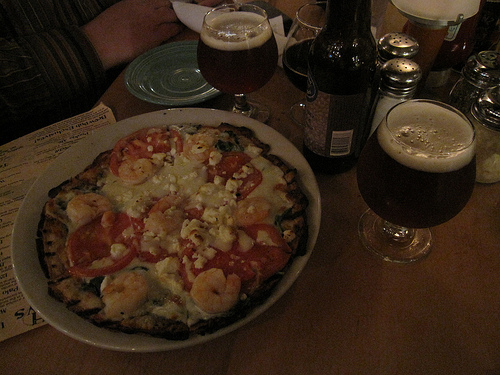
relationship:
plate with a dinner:
[11, 110, 313, 350] [39, 122, 306, 339]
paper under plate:
[2, 113, 34, 345] [11, 110, 313, 350]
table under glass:
[367, 225, 493, 287] [363, 93, 485, 274]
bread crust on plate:
[129, 315, 188, 338] [11, 110, 313, 350]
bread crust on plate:
[227, 290, 274, 315] [11, 110, 313, 350]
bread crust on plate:
[50, 144, 107, 191] [11, 110, 313, 350]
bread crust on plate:
[41, 220, 84, 304] [11, 110, 313, 350]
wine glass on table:
[358, 85, 486, 282] [20, 25, 487, 365]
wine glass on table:
[188, 4, 355, 120] [20, 25, 487, 365]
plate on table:
[11, 110, 313, 350] [20, 25, 487, 365]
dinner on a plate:
[32, 122, 311, 341] [11, 110, 313, 350]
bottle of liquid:
[300, 0, 375, 175] [316, 0, 376, 174]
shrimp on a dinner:
[191, 267, 240, 313] [32, 122, 311, 341]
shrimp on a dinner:
[101, 270, 143, 314] [32, 122, 311, 341]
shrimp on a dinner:
[67, 189, 114, 228] [32, 122, 311, 341]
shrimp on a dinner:
[238, 192, 268, 230] [32, 122, 311, 341]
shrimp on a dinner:
[143, 201, 180, 238] [32, 122, 311, 341]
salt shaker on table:
[382, 55, 422, 130] [441, 219, 480, 254]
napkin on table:
[159, 0, 296, 70] [270, 183, 400, 364]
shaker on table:
[441, 47, 499, 112] [156, 215, 498, 362]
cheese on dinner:
[103, 149, 246, 266] [32, 122, 311, 341]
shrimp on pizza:
[191, 267, 240, 313] [28, 91, 324, 345]